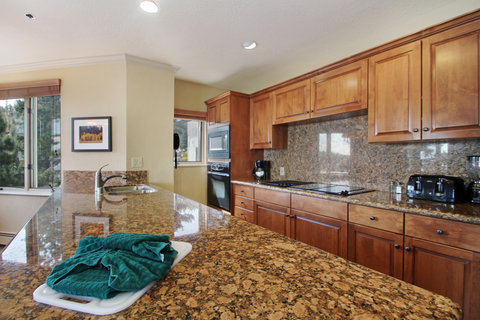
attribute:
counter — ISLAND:
[1, 170, 462, 317]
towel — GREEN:
[69, 229, 147, 280]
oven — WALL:
[209, 168, 233, 205]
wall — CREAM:
[122, 60, 178, 181]